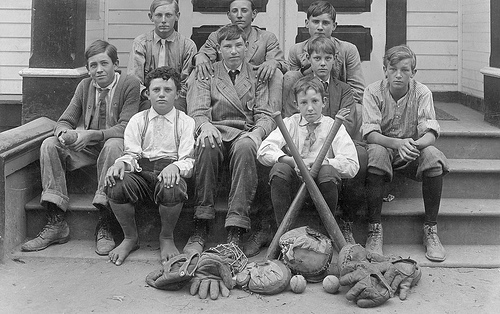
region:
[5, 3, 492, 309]
Photo is in black and white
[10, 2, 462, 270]
A group of kids in the foreground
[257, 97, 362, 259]
Baseball bats are in front of the kids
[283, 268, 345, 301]
Two baseballs in the foreground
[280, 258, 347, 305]
Baseballs are on the ground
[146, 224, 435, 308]
Baseball gloves on the ground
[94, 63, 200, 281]
Young boy is barefoot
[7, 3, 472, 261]
Young boys are sitting in front of building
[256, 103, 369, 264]
Bats are made of wood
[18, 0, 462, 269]
Young boys are looking at the camera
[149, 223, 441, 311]
baseball gloves on the floor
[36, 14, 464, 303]
boys sitting on the steps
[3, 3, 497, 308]
Black and white photograph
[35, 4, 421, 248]
Group of boys sitting on porch steps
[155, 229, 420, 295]
Pile of baseballs and gloves on ground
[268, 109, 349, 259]
Two bats crisscrossed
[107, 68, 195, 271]
Boy not wearing shoes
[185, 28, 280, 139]
Boy wearing suit jacket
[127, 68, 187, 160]
Boy wearing suspenders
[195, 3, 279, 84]
Boy with hands on shoulders of boy in front of him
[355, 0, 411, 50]
White door with black trim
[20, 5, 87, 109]
Black column with white trim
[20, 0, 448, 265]
the group of boys posing for a picture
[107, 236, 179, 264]
the boy's bare feet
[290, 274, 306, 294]
the baseball on the ground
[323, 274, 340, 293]
the baseball on the ground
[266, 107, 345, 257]
the two bats in front of the boy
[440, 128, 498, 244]
the empty stairs next to the boy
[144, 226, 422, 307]
the baseball gear on the ground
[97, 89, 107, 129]
the long tie on the boy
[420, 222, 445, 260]
the shoe on the boy's foot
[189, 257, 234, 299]
the catcher's mitt on the ground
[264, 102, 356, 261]
two bats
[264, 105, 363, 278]
bats are crossed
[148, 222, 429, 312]
baseball gloves are on the ground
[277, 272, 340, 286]
baseball balls are on the ground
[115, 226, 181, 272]
boy does not have shoes on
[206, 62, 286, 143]
boy is wearing a suit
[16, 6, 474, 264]
group of boys sitting on the steps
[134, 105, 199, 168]
boy is wearing suspenders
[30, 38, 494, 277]
picture is in black and white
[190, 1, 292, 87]
boy has his hands on the boy in front of him